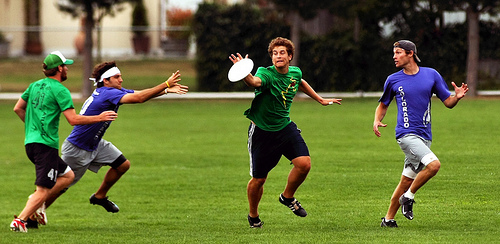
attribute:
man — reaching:
[228, 37, 342, 226]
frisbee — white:
[228, 58, 253, 83]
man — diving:
[27, 60, 190, 230]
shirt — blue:
[66, 86, 134, 152]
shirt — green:
[242, 65, 302, 132]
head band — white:
[89, 60, 122, 87]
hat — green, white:
[42, 54, 74, 71]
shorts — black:
[25, 141, 69, 188]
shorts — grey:
[60, 136, 122, 187]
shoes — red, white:
[10, 208, 48, 233]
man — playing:
[373, 40, 469, 229]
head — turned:
[391, 41, 416, 67]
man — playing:
[9, 50, 118, 232]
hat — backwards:
[393, 39, 420, 64]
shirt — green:
[21, 77, 76, 149]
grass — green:
[2, 55, 500, 243]